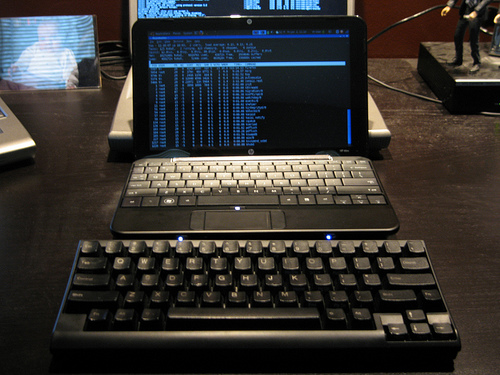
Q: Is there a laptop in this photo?
A: Yes, there is a laptop.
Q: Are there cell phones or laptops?
A: Yes, there is a laptop.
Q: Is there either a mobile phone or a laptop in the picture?
A: Yes, there is a laptop.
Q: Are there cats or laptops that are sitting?
A: Yes, the laptop is sitting.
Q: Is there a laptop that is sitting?
A: Yes, there is a laptop that is sitting.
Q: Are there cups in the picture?
A: No, there are no cups.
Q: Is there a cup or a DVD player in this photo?
A: No, there are no cups or DVD players.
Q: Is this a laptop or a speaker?
A: This is a laptop.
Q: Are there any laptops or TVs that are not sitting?
A: No, there is a laptop but it is sitting.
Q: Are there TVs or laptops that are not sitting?
A: No, there is a laptop but it is sitting.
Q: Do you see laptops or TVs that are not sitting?
A: No, there is a laptop but it is sitting.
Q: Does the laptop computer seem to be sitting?
A: Yes, the laptop computer is sitting.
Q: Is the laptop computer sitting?
A: Yes, the laptop computer is sitting.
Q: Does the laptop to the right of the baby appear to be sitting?
A: Yes, the laptop is sitting.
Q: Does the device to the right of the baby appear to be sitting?
A: Yes, the laptop is sitting.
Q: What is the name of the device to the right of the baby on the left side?
A: The device is a laptop.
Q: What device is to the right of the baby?
A: The device is a laptop.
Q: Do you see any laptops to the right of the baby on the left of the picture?
A: Yes, there is a laptop to the right of the baby.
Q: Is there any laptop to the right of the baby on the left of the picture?
A: Yes, there is a laptop to the right of the baby.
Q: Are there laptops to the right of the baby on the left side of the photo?
A: Yes, there is a laptop to the right of the baby.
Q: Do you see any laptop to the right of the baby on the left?
A: Yes, there is a laptop to the right of the baby.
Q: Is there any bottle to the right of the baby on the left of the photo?
A: No, there is a laptop to the right of the baby.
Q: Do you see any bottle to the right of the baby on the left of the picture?
A: No, there is a laptop to the right of the baby.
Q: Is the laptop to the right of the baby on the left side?
A: Yes, the laptop is to the right of the baby.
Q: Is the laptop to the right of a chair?
A: No, the laptop is to the right of the baby.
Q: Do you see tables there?
A: Yes, there is a table.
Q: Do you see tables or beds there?
A: Yes, there is a table.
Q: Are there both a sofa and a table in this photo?
A: No, there is a table but no sofas.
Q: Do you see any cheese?
A: No, there is no cheese.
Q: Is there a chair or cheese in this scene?
A: No, there are no cheese or chairs.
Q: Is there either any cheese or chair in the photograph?
A: No, there are no cheese or chairs.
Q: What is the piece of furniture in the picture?
A: The piece of furniture is a table.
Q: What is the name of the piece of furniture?
A: The piece of furniture is a table.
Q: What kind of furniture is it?
A: The piece of furniture is a table.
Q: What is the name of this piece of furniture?
A: That is a table.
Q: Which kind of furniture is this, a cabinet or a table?
A: That is a table.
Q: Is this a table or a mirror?
A: This is a table.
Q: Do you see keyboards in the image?
A: Yes, there is a keyboard.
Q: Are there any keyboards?
A: Yes, there is a keyboard.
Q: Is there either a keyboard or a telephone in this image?
A: Yes, there is a keyboard.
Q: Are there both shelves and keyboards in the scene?
A: No, there is a keyboard but no shelves.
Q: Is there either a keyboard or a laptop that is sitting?
A: Yes, the keyboard is sitting.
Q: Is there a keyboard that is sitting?
A: Yes, there is a keyboard that is sitting.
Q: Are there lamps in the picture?
A: No, there are no lamps.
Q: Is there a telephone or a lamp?
A: No, there are no lamps or phones.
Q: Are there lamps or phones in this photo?
A: No, there are no lamps or phones.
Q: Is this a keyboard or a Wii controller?
A: This is a keyboard.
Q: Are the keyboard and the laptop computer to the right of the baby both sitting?
A: Yes, both the keyboard and the laptop computer are sitting.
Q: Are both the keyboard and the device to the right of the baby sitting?
A: Yes, both the keyboard and the laptop computer are sitting.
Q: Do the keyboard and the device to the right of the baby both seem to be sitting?
A: Yes, both the keyboard and the laptop computer are sitting.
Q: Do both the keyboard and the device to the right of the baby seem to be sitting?
A: Yes, both the keyboard and the laptop computer are sitting.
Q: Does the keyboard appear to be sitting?
A: Yes, the keyboard is sitting.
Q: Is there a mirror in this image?
A: No, there are no mirrors.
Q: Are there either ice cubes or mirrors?
A: No, there are no mirrors or ice cubes.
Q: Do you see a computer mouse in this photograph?
A: Yes, there is a computer mouse.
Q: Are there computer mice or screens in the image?
A: Yes, there is a computer mouse.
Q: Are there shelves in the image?
A: No, there are no shelves.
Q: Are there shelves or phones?
A: No, there are no shelves or phones.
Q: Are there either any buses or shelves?
A: No, there are no shelves or buses.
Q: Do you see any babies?
A: Yes, there is a baby.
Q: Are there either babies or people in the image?
A: Yes, there is a baby.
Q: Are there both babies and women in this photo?
A: No, there is a baby but no women.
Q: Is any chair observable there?
A: No, there are no chairs.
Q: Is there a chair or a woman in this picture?
A: No, there are no chairs or women.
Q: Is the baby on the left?
A: Yes, the baby is on the left of the image.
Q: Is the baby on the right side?
A: No, the baby is on the left of the image.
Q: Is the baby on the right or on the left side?
A: The baby is on the left of the image.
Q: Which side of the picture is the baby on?
A: The baby is on the left of the image.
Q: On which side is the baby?
A: The baby is on the left of the image.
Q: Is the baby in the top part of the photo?
A: Yes, the baby is in the top of the image.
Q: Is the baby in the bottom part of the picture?
A: No, the baby is in the top of the image.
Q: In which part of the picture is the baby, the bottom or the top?
A: The baby is in the top of the image.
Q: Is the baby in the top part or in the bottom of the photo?
A: The baby is in the top of the image.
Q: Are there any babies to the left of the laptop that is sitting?
A: Yes, there is a baby to the left of the laptop.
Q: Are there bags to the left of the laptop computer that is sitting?
A: No, there is a baby to the left of the laptop.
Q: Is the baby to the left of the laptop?
A: Yes, the baby is to the left of the laptop.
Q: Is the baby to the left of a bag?
A: No, the baby is to the left of the laptop.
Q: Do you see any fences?
A: No, there are no fences.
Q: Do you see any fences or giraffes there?
A: No, there are no fences or giraffes.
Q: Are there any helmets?
A: No, there are no helmets.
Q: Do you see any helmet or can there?
A: No, there are no helmets or cans.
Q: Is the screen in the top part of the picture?
A: Yes, the screen is in the top of the image.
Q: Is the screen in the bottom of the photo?
A: No, the screen is in the top of the image.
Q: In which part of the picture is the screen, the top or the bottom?
A: The screen is in the top of the image.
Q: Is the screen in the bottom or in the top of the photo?
A: The screen is in the top of the image.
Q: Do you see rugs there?
A: No, there are no rugs.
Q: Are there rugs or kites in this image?
A: No, there are no rugs or kites.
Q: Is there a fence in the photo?
A: No, there are no fences.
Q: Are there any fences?
A: No, there are no fences.